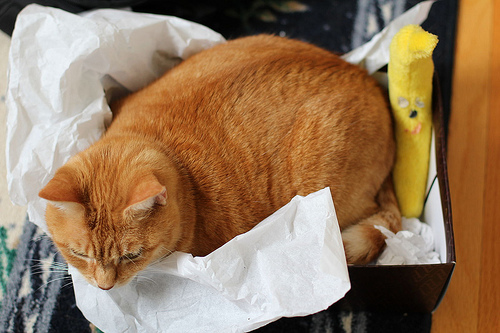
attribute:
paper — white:
[5, 3, 352, 331]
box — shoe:
[327, 63, 456, 312]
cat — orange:
[45, 53, 407, 288]